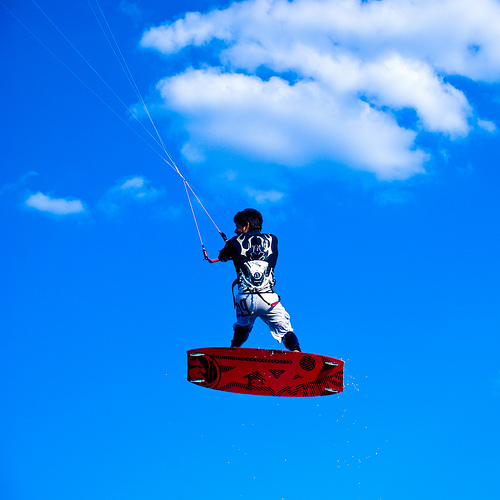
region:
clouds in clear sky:
[246, 81, 402, 213]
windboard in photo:
[176, 353, 358, 391]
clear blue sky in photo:
[20, 344, 142, 456]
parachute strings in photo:
[85, 66, 225, 248]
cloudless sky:
[48, 271, 159, 428]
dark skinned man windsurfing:
[219, 188, 292, 280]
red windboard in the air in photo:
[134, 290, 364, 407]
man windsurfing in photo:
[161, 182, 364, 409]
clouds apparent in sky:
[205, 99, 428, 199]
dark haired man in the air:
[165, 170, 379, 445]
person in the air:
[170, 197, 356, 410]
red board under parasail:
[181, 342, 355, 405]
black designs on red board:
[228, 356, 310, 390]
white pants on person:
[231, 289, 296, 341]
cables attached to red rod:
[188, 212, 233, 266]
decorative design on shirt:
[234, 235, 275, 294]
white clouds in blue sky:
[354, 123, 452, 215]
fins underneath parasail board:
[182, 345, 213, 392]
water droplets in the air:
[338, 359, 365, 407]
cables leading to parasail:
[163, 157, 205, 221]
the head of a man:
[230, 200, 267, 242]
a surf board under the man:
[176, 342, 353, 402]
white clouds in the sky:
[121, 0, 496, 242]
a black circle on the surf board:
[296, 351, 318, 373]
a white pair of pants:
[229, 290, 300, 345]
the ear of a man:
[240, 217, 254, 236]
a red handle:
[199, 245, 234, 271]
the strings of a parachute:
[1, 0, 232, 252]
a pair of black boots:
[226, 323, 313, 353]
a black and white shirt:
[214, 230, 287, 297]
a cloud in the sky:
[98, 170, 164, 225]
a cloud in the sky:
[18, 187, 89, 233]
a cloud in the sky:
[164, 70, 410, 211]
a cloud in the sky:
[185, 145, 287, 232]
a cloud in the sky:
[396, 75, 491, 155]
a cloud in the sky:
[148, 10, 212, 54]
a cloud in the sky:
[231, 30, 382, 92]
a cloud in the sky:
[259, 0, 405, 55]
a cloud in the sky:
[418, 4, 498, 88]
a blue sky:
[1, 228, 496, 494]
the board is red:
[183, 343, 345, 411]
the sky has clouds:
[11, 0, 498, 272]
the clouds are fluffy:
[12, 0, 499, 264]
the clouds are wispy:
[16, 0, 495, 330]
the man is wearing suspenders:
[223, 278, 305, 329]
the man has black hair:
[236, 210, 263, 237]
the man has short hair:
[218, 207, 277, 247]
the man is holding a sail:
[46, 51, 237, 254]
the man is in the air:
[189, 202, 346, 409]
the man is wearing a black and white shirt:
[213, 231, 306, 302]